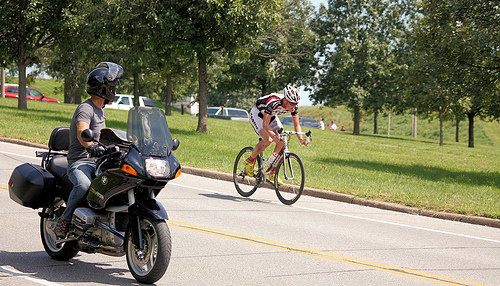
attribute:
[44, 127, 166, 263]
motorcycle — still, moving, close, black, large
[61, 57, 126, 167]
man — riding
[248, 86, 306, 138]
person — white, active, riding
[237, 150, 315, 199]
bike — white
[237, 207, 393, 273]
road — paved, white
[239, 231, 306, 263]
line — yellow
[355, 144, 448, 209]
grass — short, cut, green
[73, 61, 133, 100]
helmet — black